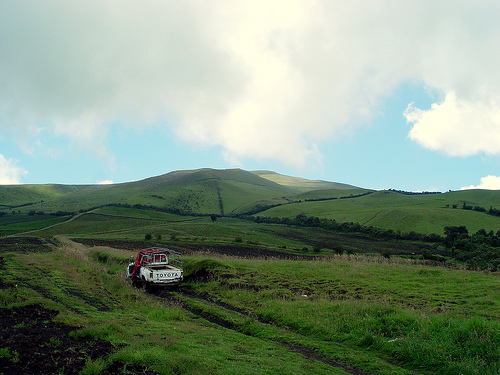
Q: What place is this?
A: It is a field.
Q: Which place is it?
A: It is a field.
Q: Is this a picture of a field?
A: Yes, it is showing a field.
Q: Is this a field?
A: Yes, it is a field.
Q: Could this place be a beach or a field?
A: It is a field.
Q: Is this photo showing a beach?
A: No, the picture is showing a field.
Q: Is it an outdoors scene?
A: Yes, it is outdoors.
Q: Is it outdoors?
A: Yes, it is outdoors.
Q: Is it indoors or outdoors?
A: It is outdoors.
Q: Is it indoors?
A: No, it is outdoors.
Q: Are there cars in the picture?
A: No, there are no cars.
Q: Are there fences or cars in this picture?
A: No, there are no cars or fences.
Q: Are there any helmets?
A: No, there are no helmets.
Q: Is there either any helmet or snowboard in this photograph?
A: No, there are no helmets or snowboards.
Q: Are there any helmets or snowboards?
A: No, there are no helmets or snowboards.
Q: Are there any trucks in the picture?
A: Yes, there is a truck.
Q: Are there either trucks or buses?
A: Yes, there is a truck.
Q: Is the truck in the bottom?
A: Yes, the truck is in the bottom of the image.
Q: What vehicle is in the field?
A: The vehicle is a truck.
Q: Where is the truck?
A: The truck is in the field.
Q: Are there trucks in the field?
A: Yes, there is a truck in the field.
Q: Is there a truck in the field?
A: Yes, there is a truck in the field.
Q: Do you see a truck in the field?
A: Yes, there is a truck in the field.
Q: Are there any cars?
A: No, there are no cars.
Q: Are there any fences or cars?
A: No, there are no cars or fences.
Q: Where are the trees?
A: The trees are in the field.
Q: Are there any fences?
A: No, there are no fences.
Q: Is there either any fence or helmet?
A: No, there are no fences or helmets.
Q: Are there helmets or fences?
A: No, there are no fences or helmets.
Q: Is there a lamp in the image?
A: No, there are no lamps.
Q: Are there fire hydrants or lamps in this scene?
A: No, there are no lamps or fire hydrants.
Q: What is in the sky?
A: The clouds are in the sky.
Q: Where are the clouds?
A: The clouds are in the sky.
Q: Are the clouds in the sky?
A: Yes, the clouds are in the sky.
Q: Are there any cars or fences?
A: No, there are no cars or fences.